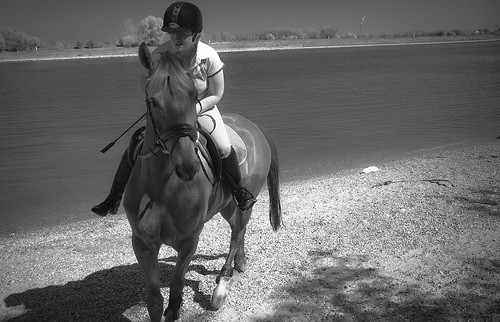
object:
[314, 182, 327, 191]
pebbles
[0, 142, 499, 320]
beach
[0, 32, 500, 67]
coast line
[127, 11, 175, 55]
trees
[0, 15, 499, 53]
distance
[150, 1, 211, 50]
helmet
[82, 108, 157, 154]
crop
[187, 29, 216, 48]
ear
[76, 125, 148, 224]
riding boots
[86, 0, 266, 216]
female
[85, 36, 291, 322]
horse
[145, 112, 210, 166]
bridle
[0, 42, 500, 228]
water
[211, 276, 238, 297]
white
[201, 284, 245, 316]
hoof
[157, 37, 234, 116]
white shirt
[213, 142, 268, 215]
riding boots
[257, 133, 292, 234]
tail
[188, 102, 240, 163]
pants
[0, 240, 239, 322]
shadow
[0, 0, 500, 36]
sky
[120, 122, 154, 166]
rope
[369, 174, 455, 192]
branch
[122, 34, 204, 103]
mane